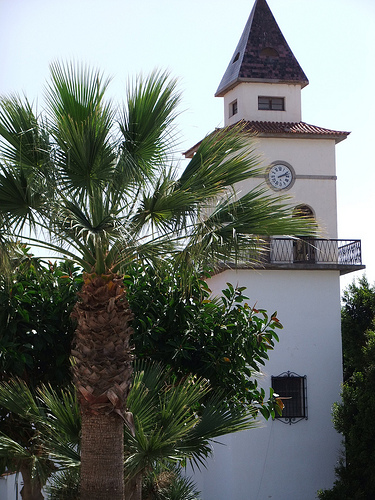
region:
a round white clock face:
[267, 160, 296, 191]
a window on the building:
[264, 364, 309, 425]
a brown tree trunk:
[72, 278, 124, 495]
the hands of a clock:
[273, 166, 288, 176]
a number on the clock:
[274, 160, 279, 170]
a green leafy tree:
[0, 51, 330, 291]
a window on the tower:
[255, 92, 286, 113]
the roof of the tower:
[207, 1, 316, 100]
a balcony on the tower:
[200, 233, 370, 269]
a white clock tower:
[159, 2, 364, 496]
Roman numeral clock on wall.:
[265, 158, 294, 192]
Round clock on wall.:
[267, 161, 294, 193]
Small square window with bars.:
[268, 370, 309, 428]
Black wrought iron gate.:
[228, 236, 363, 267]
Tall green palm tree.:
[14, 101, 337, 496]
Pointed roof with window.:
[212, 0, 313, 99]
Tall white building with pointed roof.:
[154, 2, 370, 498]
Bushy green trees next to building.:
[318, 274, 373, 498]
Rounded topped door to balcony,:
[293, 202, 317, 266]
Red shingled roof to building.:
[176, 119, 353, 158]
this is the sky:
[45, 18, 201, 49]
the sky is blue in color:
[317, 63, 365, 100]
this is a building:
[211, 1, 369, 483]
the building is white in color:
[239, 445, 311, 494]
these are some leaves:
[17, 121, 157, 169]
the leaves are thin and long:
[126, 76, 179, 158]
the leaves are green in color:
[132, 100, 149, 117]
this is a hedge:
[343, 373, 374, 498]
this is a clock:
[262, 161, 297, 186]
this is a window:
[271, 370, 304, 416]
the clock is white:
[237, 144, 329, 219]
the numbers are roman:
[253, 146, 308, 194]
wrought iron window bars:
[256, 355, 335, 441]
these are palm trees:
[42, 291, 247, 481]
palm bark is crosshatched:
[84, 381, 121, 433]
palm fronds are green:
[144, 402, 197, 440]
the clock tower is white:
[168, 23, 363, 302]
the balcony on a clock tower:
[166, 153, 370, 279]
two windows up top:
[198, 56, 321, 118]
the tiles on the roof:
[211, 93, 340, 159]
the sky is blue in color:
[117, 10, 197, 45]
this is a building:
[253, 17, 328, 195]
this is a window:
[259, 96, 286, 108]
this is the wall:
[289, 271, 334, 360]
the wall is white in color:
[289, 300, 298, 335]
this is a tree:
[143, 293, 250, 386]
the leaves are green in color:
[174, 318, 247, 355]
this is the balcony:
[306, 235, 366, 263]